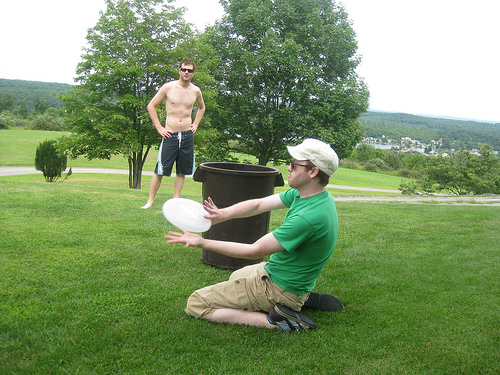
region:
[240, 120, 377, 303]
man with white hat and green shirt playing frisbee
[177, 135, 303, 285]
dark garbage can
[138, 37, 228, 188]
man with no shirt and black shorts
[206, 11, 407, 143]
large tree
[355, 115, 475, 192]
buildings and trees in distance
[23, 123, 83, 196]
small tree in distance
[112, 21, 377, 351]
men playing frisbee in park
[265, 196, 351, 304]
green shirt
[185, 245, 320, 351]
beige pants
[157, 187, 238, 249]
white frisbee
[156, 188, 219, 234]
Man is catching a Frisbee.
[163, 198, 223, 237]
The Frisbee is white.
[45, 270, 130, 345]
The grass is green.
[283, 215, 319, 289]
The shirt is green.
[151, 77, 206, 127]
The man has no shirt.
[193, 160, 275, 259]
Trashcan between the men.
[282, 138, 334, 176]
Man is wearing a hat.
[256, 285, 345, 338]
The shoes are black and blue.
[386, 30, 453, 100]
The sky is white.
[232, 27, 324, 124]
The tree is green.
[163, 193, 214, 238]
white frisbee in air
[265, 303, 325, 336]
tennis shoe on man's foot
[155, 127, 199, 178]
shorts on man's body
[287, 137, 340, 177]
hat on man's head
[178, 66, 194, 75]
sunglasses on man's face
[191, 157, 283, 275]
trashcan sitting in grass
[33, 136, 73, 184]
bush growing in grass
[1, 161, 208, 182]
sidewalk running through park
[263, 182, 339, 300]
green t-shirt on man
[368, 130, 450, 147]
city's buildings on horizon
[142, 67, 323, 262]
Two men tossing frisbee in field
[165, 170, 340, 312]
Man in green shirt and khaki shorts catches frisbee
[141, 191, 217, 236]
White frisbee in the air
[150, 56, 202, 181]
Shirtless man stands in grass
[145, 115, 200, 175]
Man wearing black and white shorts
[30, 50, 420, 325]
Large field with well-maintained grass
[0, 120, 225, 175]
Sidewalk cutting through the field of grass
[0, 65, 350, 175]
Landscaped trees in the field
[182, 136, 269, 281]
Large brown trash can in middle of field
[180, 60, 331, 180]
Both men are wearing sunglasses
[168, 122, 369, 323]
person on the ground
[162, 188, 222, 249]
Frisbee in the air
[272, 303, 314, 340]
shoes on the man's feet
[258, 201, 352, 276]
green shirt on man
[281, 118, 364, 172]
hat on the man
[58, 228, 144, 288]
green grass next to man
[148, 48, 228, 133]
man without a shirt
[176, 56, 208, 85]
man with sunglasses on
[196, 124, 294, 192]
trash can next to people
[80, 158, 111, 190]
sidewalk next to people